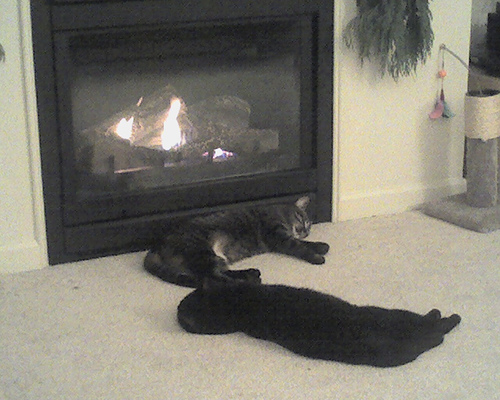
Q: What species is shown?
A: Cats.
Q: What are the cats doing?
A: Sleeping.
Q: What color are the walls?
A: Eggshell white.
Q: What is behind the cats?
A: Fire.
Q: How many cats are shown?
A: Two.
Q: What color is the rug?
A: Cream.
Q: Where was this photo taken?
A: In front of a fireplace.